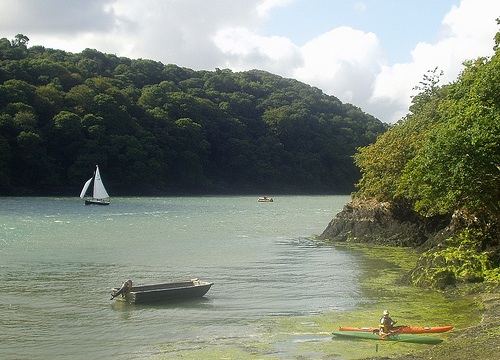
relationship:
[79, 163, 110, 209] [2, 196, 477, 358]
sailboat in bay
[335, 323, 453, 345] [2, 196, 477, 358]
kayak in bay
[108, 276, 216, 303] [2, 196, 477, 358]
boat in bay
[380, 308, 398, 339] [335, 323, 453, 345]
person in kayak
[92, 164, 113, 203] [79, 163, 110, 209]
drap on sailboat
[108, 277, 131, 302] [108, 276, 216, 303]
motor on boat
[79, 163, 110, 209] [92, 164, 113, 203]
sailboat with drap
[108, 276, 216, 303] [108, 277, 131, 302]
boat with motor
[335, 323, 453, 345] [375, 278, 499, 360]
kayak on shore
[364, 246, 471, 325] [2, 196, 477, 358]
algae in bay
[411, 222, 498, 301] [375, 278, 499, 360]
rock on shore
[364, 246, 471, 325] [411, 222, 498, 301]
algae on rock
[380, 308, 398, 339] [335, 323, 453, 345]
person on kayak